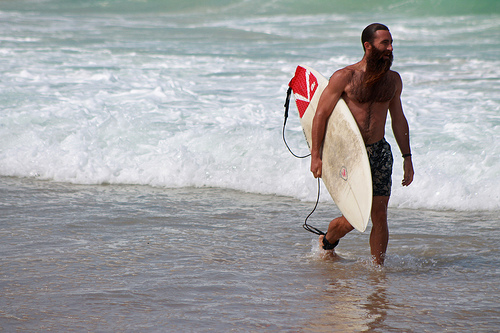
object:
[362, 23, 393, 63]
head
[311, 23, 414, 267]
man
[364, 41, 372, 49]
ear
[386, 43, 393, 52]
nose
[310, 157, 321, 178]
hand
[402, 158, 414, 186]
hand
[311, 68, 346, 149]
arm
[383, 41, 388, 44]
eye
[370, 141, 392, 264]
leg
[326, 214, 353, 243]
leg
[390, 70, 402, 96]
shoulder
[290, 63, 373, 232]
surfboard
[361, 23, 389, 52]
hair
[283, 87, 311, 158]
wire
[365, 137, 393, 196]
shorts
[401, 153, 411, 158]
band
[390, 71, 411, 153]
arm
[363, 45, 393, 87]
beard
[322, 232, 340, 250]
band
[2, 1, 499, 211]
wave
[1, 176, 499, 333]
beach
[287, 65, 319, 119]
logo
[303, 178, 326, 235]
leash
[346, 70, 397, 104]
chest